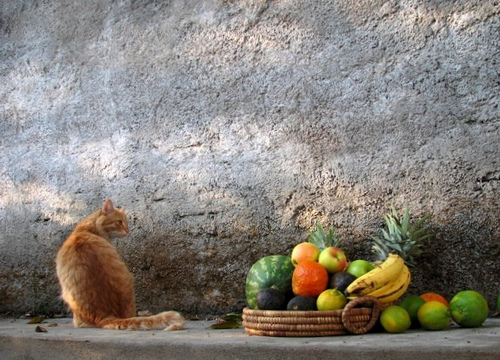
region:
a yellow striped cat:
[46, 197, 167, 333]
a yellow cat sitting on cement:
[33, 172, 199, 352]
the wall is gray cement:
[16, 56, 336, 149]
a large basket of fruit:
[232, 220, 417, 337]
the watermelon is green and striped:
[249, 252, 289, 311]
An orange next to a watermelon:
[262, 259, 328, 301]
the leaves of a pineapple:
[382, 203, 429, 258]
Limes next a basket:
[337, 305, 451, 334]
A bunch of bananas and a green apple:
[346, 259, 406, 306]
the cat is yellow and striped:
[49, 202, 158, 332]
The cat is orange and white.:
[53, 198, 184, 330]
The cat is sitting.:
[55, 197, 185, 330]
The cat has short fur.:
[53, 198, 185, 331]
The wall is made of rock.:
[0, 0, 499, 322]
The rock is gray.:
[0, 0, 499, 320]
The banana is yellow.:
[347, 252, 412, 304]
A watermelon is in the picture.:
[245, 251, 293, 308]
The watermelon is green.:
[244, 253, 291, 308]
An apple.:
[316, 246, 346, 271]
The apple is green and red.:
[318, 247, 348, 272]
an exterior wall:
[5, 4, 495, 311]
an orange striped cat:
[56, 198, 183, 331]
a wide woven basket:
[241, 296, 378, 337]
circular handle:
[340, 292, 380, 334]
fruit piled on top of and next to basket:
[239, 204, 490, 340]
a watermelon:
[246, 251, 292, 308]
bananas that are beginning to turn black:
[346, 252, 411, 303]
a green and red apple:
[318, 246, 346, 273]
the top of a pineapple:
[371, 199, 440, 267]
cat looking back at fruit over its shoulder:
[53, 196, 489, 332]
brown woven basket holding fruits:
[239, 305, 374, 337]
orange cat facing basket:
[58, 200, 177, 328]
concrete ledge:
[8, 320, 463, 359]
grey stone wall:
[0, 0, 499, 305]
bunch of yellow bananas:
[353, 253, 406, 304]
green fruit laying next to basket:
[380, 293, 489, 328]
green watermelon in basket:
[248, 253, 296, 308]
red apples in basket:
[295, 243, 337, 288]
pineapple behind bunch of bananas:
[376, 213, 421, 276]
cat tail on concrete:
[115, 315, 184, 330]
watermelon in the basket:
[250, 254, 271, 318]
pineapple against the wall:
[411, 180, 429, 297]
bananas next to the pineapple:
[377, 260, 384, 303]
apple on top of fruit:
[317, 247, 341, 275]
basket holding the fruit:
[262, 300, 337, 330]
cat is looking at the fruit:
[70, 200, 105, 340]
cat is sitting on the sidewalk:
[40, 265, 110, 350]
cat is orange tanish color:
[95, 250, 170, 322]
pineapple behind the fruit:
[300, 196, 330, 262]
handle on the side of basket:
[337, 285, 389, 330]